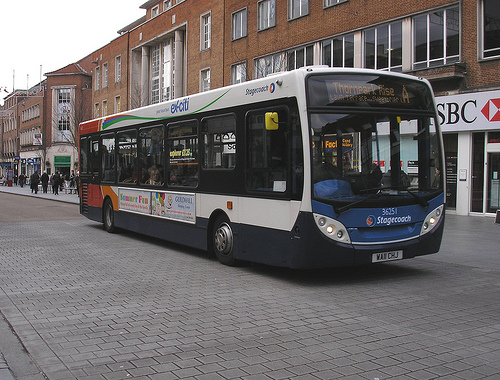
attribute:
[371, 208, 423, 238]
writing — white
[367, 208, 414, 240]
writing — white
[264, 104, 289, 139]
mirror — yellow, side-view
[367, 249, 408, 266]
license plate — white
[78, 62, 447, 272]
bus — tour, giant, white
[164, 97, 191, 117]
writing — blue